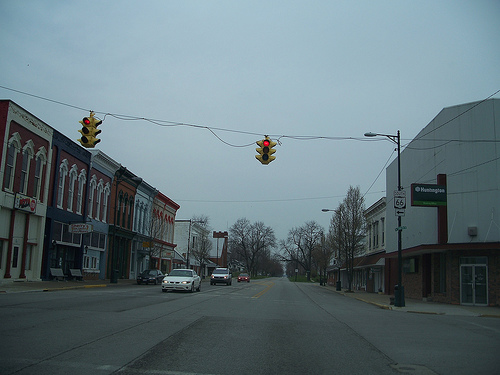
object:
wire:
[149, 117, 375, 144]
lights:
[76, 111, 278, 166]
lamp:
[363, 129, 406, 307]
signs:
[409, 182, 450, 208]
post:
[390, 129, 406, 307]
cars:
[161, 267, 251, 293]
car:
[136, 269, 163, 285]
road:
[0, 275, 499, 374]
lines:
[251, 277, 282, 298]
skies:
[0, 1, 500, 275]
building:
[326, 98, 499, 307]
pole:
[335, 207, 341, 291]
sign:
[394, 198, 406, 209]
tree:
[139, 183, 372, 293]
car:
[162, 269, 202, 293]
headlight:
[162, 280, 191, 284]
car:
[237, 273, 250, 283]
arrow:
[397, 211, 404, 215]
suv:
[210, 267, 233, 286]